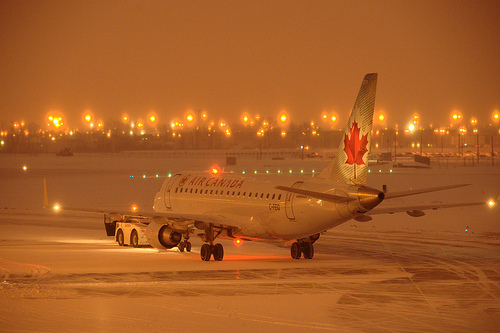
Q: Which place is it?
A: It is an airport.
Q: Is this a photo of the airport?
A: Yes, it is showing the airport.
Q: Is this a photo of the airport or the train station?
A: It is showing the airport.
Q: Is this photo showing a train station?
A: No, the picture is showing an airport.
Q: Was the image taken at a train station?
A: No, the picture was taken in an airport.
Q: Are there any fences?
A: No, there are no fences.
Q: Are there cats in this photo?
A: No, there are no cats.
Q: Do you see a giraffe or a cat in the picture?
A: No, there are no cats or giraffes.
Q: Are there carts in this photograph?
A: No, there are no carts.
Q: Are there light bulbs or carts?
A: No, there are no carts or light bulbs.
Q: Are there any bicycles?
A: No, there are no bicycles.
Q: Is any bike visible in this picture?
A: No, there are no bikes.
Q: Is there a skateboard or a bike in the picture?
A: No, there are no bikes or skateboards.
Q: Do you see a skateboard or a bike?
A: No, there are no bikes or skateboards.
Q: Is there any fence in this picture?
A: No, there are no fences.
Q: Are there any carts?
A: No, there are no carts.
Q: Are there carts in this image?
A: No, there are no carts.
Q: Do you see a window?
A: Yes, there is a window.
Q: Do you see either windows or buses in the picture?
A: Yes, there is a window.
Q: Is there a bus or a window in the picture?
A: Yes, there is a window.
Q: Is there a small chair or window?
A: Yes, there is a small window.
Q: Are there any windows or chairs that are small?
A: Yes, the window is small.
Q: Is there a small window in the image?
A: Yes, there is a small window.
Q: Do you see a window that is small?
A: Yes, there is a window that is small.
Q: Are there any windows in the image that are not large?
A: Yes, there is a small window.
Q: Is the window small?
A: Yes, the window is small.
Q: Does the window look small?
A: Yes, the window is small.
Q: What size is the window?
A: The window is small.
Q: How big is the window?
A: The window is small.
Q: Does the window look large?
A: No, the window is small.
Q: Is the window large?
A: No, the window is small.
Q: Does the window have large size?
A: No, the window is small.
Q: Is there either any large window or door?
A: No, there is a window but it is small.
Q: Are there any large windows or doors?
A: No, there is a window but it is small.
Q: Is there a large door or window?
A: No, there is a window but it is small.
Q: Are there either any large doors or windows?
A: No, there is a window but it is small.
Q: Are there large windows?
A: No, there is a window but it is small.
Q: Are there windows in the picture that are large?
A: No, there is a window but it is small.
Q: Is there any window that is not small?
A: No, there is a window but it is small.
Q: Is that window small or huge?
A: The window is small.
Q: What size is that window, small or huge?
A: The window is small.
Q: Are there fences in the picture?
A: No, there are no fences.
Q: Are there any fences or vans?
A: No, there are no fences or vans.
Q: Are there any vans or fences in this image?
A: No, there are no fences or vans.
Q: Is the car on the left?
A: Yes, the car is on the left of the image.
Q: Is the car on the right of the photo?
A: No, the car is on the left of the image.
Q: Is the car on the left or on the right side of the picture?
A: The car is on the left of the image.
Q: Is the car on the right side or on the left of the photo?
A: The car is on the left of the image.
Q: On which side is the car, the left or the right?
A: The car is on the left of the image.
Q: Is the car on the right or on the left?
A: The car is on the left of the image.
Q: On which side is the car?
A: The car is on the left of the image.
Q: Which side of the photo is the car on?
A: The car is on the left of the image.